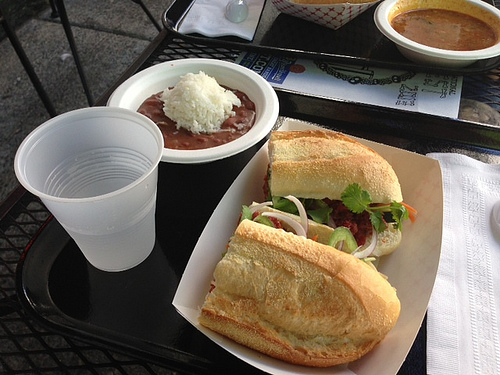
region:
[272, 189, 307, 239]
the onions are white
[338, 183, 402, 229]
the parsley is green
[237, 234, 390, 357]
the bread is tan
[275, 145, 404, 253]
vegetables on the sandwich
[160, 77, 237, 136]
rice on the beans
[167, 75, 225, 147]
the rice is white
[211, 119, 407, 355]
sandwich on a food tray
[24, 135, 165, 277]
plastic cup with water in it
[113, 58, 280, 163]
rice and beans in a bowl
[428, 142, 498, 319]
white napkins on a table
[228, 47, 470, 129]
menu on the tray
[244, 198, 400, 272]
onions on the sandwich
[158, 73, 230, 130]
rice on top of beans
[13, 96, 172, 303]
plastic cup on a black tray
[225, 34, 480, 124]
menu under the tray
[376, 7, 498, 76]
chili in a bowl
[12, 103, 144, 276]
cup on a tray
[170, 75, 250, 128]
rice in a bowl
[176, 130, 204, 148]
beans in a bowl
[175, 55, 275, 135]
bowl on a tray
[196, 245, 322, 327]
bun on in a tray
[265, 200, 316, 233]
vegetable on a bun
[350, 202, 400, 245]
vegetable in a tray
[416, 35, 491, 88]
bowl on a tray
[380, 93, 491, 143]
tray on a table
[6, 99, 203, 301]
plastic cup of water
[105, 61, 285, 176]
white bowl of bean soup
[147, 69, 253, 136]
white rice on bean soup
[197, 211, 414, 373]
bread roll on plate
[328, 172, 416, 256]
cilantro on roll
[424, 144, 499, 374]
white paper napkin on tray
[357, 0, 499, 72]
white bowl soup on tray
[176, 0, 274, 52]
white paper napkin on tray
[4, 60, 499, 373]
black tray on table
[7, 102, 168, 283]
the cup is color white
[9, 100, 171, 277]
the cup has water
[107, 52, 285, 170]
a white cup with brown beans and rice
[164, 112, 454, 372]
two sandwiches in a bowl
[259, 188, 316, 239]
the slice of onions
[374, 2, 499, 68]
a white cup of beans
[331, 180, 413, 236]
green leaves in a sandwich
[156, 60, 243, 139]
white rice on beans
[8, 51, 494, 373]
food over black pan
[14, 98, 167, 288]
the water in a cup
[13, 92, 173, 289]
clear cup with water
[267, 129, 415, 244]
half sandwich with roast beef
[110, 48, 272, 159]
white bowl with chili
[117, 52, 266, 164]
bowl with chili and white rice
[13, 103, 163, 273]
the cup is white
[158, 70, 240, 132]
the scoop of white rice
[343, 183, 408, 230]
the cilantro is green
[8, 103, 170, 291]
a plastic white cup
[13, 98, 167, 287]
water in a plastic cup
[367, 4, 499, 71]
a white dish with soup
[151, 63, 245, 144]
white rice on beans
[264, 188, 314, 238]
slice of onions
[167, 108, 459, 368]
a container with two sanwiches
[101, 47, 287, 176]
a white bowl with beans and rice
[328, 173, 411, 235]
leaves of coriander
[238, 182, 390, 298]
onions and pepper in a bread